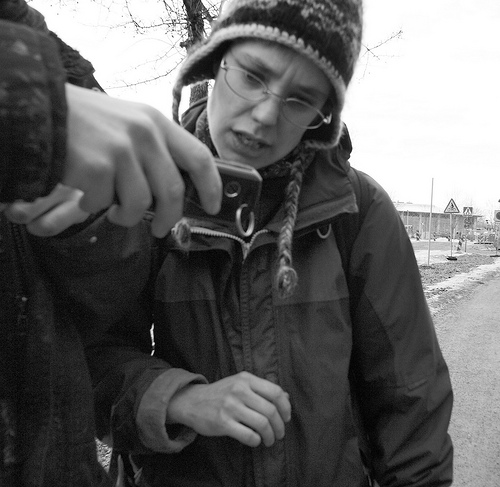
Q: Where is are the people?
A: At the sidewalk.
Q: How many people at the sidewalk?
A: Two.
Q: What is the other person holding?
A: A phone.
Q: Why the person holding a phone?
A: To show something to the other girl.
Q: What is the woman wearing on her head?
A: A benie.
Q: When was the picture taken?
A: Daytime.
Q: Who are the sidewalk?
A: People.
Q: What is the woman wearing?
A: A jacket.